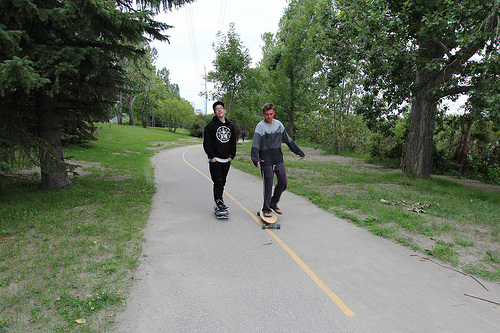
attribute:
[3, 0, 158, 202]
tree — big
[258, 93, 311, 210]
boy — three color 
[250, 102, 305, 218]
boy — young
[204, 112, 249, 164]
sweatshirt — dark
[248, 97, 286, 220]
boy — young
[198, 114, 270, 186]
hoodie — OBEY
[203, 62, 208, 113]
pole — tall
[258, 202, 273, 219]
feet — both 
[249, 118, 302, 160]
sweater — black, dark gray, light gray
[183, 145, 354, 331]
line — yellow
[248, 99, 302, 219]
they —  skateboarding 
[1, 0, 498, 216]
trees — green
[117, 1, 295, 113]
sky — white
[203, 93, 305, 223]
people —  skateboarding 